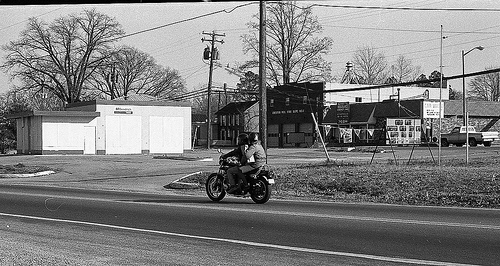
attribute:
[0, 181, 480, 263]
road — clear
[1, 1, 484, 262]
photo — black, white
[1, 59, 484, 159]
town — small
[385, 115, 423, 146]
sign — unclear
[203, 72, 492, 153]
buildings — pictured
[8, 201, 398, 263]
line — white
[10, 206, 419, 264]
line — white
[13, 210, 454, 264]
line — white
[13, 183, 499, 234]
line — white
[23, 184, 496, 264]
road — clear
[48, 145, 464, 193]
road — clear